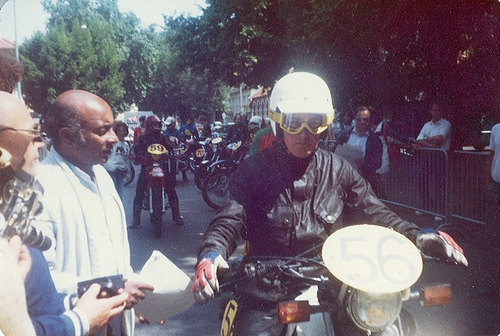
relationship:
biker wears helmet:
[191, 67, 463, 336] [258, 67, 335, 146]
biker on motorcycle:
[191, 67, 463, 336] [197, 239, 460, 335]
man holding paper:
[31, 78, 186, 335] [128, 251, 199, 336]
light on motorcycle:
[344, 287, 413, 333] [197, 239, 460, 335]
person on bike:
[133, 114, 187, 229] [142, 147, 177, 235]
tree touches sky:
[44, 2, 152, 140] [0, 4, 246, 64]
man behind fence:
[415, 99, 454, 213] [369, 139, 498, 236]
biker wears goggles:
[191, 67, 463, 336] [264, 98, 337, 136]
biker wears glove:
[191, 67, 463, 336] [190, 249, 232, 302]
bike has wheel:
[142, 147, 177, 235] [145, 184, 172, 239]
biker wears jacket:
[191, 67, 463, 336] [201, 147, 425, 292]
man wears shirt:
[31, 78, 186, 335] [41, 152, 144, 315]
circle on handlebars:
[324, 223, 427, 293] [200, 232, 495, 315]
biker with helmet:
[191, 67, 463, 336] [258, 67, 335, 146]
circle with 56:
[324, 223, 427, 293] [341, 234, 414, 285]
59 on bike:
[150, 143, 167, 158] [142, 147, 177, 235]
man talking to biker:
[31, 78, 186, 335] [191, 67, 463, 336]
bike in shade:
[142, 147, 177, 235] [112, 161, 266, 263]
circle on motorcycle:
[324, 223, 427, 293] [197, 239, 460, 335]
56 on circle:
[341, 234, 414, 285] [324, 223, 427, 293]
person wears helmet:
[133, 114, 187, 229] [145, 113, 163, 137]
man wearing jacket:
[31, 78, 186, 335] [28, 156, 147, 336]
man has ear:
[31, 78, 186, 335] [58, 128, 80, 153]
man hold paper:
[31, 78, 186, 335] [128, 251, 199, 336]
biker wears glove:
[191, 67, 463, 336] [414, 230, 473, 263]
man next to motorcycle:
[31, 78, 186, 335] [197, 239, 460, 335]